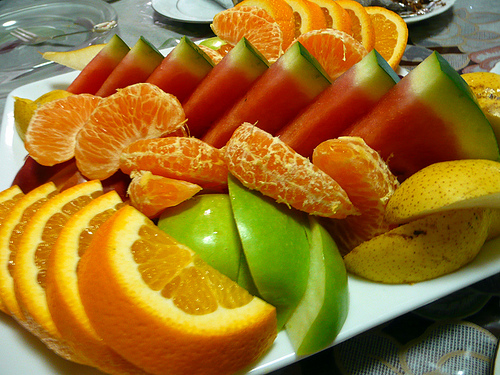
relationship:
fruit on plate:
[25, 33, 465, 327] [355, 291, 401, 327]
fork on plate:
[32, 24, 65, 56] [355, 291, 401, 327]